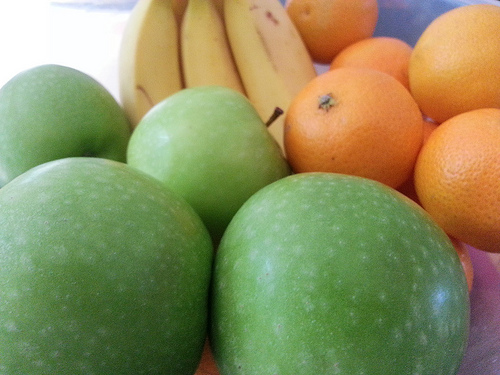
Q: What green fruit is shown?
A: Apples.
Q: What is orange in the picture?
A: Oranges.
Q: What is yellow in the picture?
A: Bananas.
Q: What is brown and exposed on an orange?
A: Stem.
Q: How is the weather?
A: Bright and sunny.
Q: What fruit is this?
A: Orange.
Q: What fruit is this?
A: Ornage.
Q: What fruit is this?
A: Apple.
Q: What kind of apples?
A: Green.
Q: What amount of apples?
A: Four.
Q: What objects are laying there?
A: Fruits.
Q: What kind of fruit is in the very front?
A: Apples.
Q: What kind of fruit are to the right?
A: Orange.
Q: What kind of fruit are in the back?
A: Bananas.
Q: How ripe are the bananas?
A: Ripe.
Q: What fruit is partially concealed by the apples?
A: Bananas.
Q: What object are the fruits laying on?
A: Table.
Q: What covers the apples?
A: Dots.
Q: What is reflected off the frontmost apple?
A: Light.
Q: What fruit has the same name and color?
A: Oranges.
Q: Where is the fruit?
A: Table.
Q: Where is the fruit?
A: Table.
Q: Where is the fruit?
A: Table.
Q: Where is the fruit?
A: Table.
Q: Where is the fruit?
A: Table.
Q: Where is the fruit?
A: Table.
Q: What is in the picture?
A: Fruits.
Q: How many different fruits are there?
A: Three.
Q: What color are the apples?
A: Green.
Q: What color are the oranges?
A: Orange.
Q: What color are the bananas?
A: Yellow.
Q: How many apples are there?
A: Four.